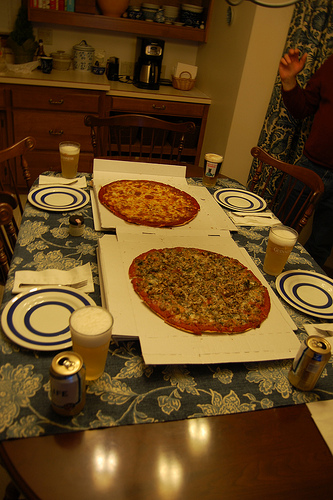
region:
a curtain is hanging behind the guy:
[249, 0, 331, 256]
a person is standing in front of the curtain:
[279, 6, 331, 260]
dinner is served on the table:
[0, 141, 331, 495]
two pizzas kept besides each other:
[93, 155, 299, 360]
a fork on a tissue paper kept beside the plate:
[213, 188, 276, 225]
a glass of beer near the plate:
[262, 218, 332, 318]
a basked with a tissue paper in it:
[172, 60, 197, 92]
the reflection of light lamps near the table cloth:
[5, 371, 332, 498]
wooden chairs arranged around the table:
[0, 113, 328, 256]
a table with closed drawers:
[0, 55, 112, 183]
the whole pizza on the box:
[97, 179, 199, 227]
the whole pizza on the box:
[127, 247, 269, 334]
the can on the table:
[49, 350, 84, 415]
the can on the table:
[287, 336, 330, 390]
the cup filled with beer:
[69, 306, 113, 380]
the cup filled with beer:
[262, 225, 298, 275]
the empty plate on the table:
[26, 184, 89, 211]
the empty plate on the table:
[213, 188, 265, 212]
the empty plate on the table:
[0, 286, 95, 350]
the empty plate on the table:
[275, 270, 332, 318]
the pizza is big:
[120, 247, 300, 343]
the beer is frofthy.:
[64, 307, 129, 384]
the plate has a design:
[8, 303, 76, 346]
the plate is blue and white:
[14, 285, 89, 362]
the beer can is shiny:
[21, 353, 102, 420]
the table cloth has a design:
[121, 378, 247, 407]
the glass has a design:
[198, 149, 237, 197]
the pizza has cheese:
[109, 169, 200, 229]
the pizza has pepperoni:
[120, 186, 180, 214]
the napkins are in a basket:
[173, 57, 216, 95]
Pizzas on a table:
[97, 169, 273, 338]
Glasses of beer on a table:
[56, 136, 310, 381]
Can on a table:
[46, 351, 91, 419]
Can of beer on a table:
[47, 346, 89, 419]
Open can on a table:
[47, 348, 90, 419]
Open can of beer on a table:
[48, 347, 89, 419]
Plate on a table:
[0, 283, 104, 351]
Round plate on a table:
[0, 285, 100, 352]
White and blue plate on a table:
[0, 283, 100, 354]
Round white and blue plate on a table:
[0, 282, 102, 355]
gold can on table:
[51, 353, 102, 417]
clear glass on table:
[70, 308, 128, 386]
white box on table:
[142, 295, 235, 380]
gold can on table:
[302, 327, 321, 395]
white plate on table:
[15, 296, 110, 361]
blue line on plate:
[42, 328, 58, 339]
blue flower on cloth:
[106, 368, 135, 431]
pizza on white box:
[167, 294, 262, 372]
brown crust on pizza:
[181, 301, 205, 332]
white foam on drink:
[73, 310, 103, 326]